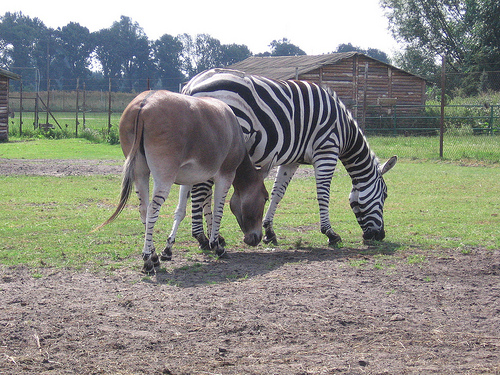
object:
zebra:
[180, 68, 400, 251]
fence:
[7, 76, 122, 138]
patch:
[0, 157, 121, 180]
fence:
[358, 102, 500, 136]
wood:
[74, 78, 81, 137]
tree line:
[0, 10, 253, 91]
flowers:
[9, 120, 73, 140]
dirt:
[0, 250, 499, 374]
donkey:
[93, 88, 271, 276]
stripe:
[146, 192, 159, 261]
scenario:
[0, 0, 500, 375]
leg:
[131, 158, 156, 250]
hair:
[87, 154, 137, 234]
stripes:
[251, 86, 283, 140]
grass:
[8, 181, 95, 266]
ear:
[377, 155, 399, 176]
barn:
[180, 51, 438, 136]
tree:
[90, 15, 153, 91]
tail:
[88, 106, 144, 235]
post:
[439, 50, 447, 157]